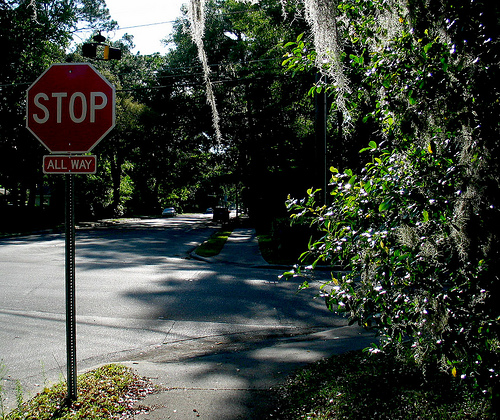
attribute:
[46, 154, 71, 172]
lettering — white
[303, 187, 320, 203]
leaves — green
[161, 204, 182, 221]
car — parked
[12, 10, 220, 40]
wire — suspended, electrical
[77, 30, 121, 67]
traffic light — suspended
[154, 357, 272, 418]
sidewalk — cement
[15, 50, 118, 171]
sign — stop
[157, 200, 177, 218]
car — in the distance, parked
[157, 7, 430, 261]
trees — green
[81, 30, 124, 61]
light — red, in the middle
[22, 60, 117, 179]
stop sign — red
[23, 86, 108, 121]
letter — white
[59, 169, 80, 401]
pole — steel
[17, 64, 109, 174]
sign — red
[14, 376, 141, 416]
grass — green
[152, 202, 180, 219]
car — parked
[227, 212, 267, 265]
sidewalk — empty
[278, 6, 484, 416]
bushes — green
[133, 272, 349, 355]
shadows — trees, black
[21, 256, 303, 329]
street — gray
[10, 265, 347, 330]
street — empty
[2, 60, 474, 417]
area — heavily shaded, residential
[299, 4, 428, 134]
moss — spanish moss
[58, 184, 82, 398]
pole — metal 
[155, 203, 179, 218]
car — parked 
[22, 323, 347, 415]
sidewalk — edge 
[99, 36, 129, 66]
light — two-way stop 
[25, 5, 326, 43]
line — power 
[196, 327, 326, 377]
area — shaded 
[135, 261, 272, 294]
sunlight — poking through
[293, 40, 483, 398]
bush — large 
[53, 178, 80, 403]
post — green 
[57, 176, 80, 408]
post — green 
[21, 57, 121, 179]
sign — stop , up, All way , red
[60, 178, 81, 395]
post — Green 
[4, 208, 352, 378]
street — side 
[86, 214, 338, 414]
sidewalk — each 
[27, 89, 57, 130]
letter — S 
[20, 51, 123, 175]
sign — stop , bottom , top 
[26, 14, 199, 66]
light — Traffic 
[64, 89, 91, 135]
letter — O 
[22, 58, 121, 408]
sign — above , stop